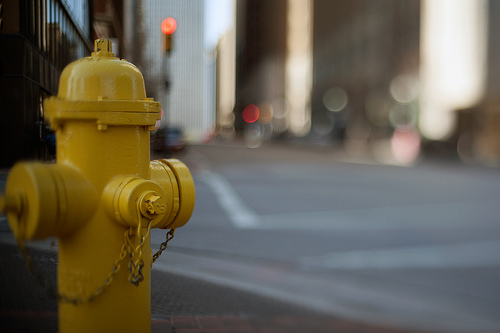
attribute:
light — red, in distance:
[155, 13, 190, 35]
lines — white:
[227, 144, 416, 269]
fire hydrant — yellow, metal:
[7, 32, 194, 326]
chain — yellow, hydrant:
[59, 205, 176, 309]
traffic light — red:
[158, 14, 177, 56]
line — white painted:
[193, 153, 262, 236]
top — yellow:
[92, 34, 114, 55]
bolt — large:
[146, 193, 169, 217]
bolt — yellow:
[2, 190, 25, 220]